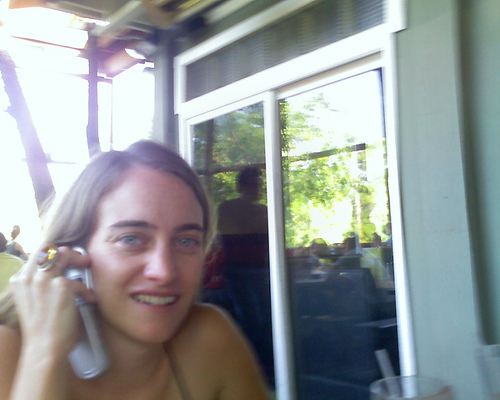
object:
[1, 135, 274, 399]
woman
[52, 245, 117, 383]
phone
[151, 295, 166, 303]
teeth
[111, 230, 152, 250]
eye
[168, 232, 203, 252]
eye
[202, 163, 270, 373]
reflection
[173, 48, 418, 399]
door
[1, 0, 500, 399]
background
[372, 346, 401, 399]
straw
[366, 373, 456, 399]
drink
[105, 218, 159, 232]
eyebrow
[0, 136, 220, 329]
hair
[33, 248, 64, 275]
ring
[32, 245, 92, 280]
finger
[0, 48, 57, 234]
woods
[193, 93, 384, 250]
trees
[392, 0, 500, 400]
wall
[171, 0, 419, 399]
frame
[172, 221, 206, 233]
eyebrow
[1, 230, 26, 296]
person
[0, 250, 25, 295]
shirt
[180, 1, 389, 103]
vent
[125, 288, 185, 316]
smile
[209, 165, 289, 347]
man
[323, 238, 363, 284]
people